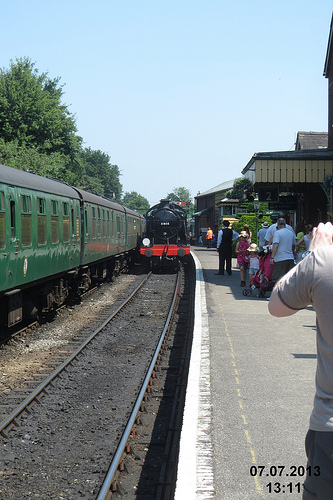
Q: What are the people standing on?
A: A platform.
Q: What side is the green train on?
A: The left.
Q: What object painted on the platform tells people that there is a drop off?
A: A white line.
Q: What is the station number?
A: 2.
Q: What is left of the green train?
A: Trees.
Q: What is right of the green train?
A: A blacks and red train.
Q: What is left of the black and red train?
A: A green train.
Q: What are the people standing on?
A: The platform.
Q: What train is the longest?
A: The green train.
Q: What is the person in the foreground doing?
A: Taking a picture.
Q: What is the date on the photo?
A: 07.07.2013.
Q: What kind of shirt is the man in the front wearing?
A: A grey t-shirt.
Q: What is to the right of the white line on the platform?
A: A yellow dashed line.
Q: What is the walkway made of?
A: Concrete.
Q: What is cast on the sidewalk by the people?
A: Shadows.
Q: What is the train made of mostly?
A: Metal.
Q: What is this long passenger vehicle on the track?
A: Train.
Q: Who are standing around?
A: Passengers.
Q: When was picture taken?
A: During daylight.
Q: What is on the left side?
A: A train.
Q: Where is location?
A: Train station.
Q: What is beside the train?
A: Train track.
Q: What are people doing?
A: Waiting to load train.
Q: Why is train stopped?
A: To load passengers.